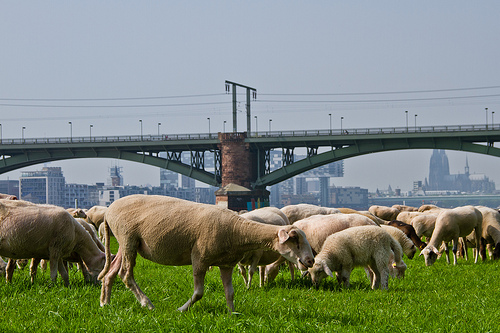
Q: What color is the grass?
A: Green.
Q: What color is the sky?
A: Blue.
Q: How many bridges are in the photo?
A: One.